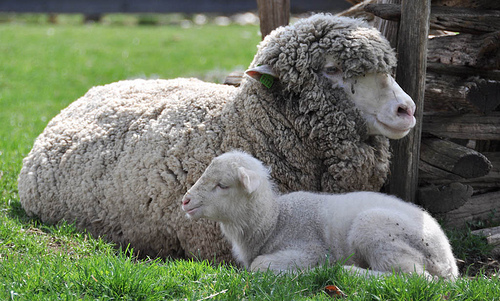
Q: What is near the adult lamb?
A: A baby lamb.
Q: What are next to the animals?
A: Stacks of wood.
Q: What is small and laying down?
A: A young lamb.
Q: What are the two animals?
A: An adult and baby lamb.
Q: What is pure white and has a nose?
A: The head of the baby lamb.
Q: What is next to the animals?
A: Wooden logs.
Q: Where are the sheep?
A: Grass field.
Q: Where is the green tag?
A: Sheep's ear.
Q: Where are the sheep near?
A: Wood structure.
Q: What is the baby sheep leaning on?
A: Adult sheep.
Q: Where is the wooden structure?
A: Next to sheep.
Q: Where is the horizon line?
A: End of field.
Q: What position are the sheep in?
A: Lying.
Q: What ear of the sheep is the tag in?
A: Right.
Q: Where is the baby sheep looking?
A: Left.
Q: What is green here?
A: Grass.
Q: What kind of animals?
A: Sheep.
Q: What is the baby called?
A: A lamb.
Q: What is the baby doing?
A: Laying down.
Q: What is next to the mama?
A: Wood pile.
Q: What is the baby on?
A: Grass.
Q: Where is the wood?
A: Next to the sheep.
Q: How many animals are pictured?
A: Two.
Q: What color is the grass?
A: Green.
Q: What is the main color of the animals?
A: White.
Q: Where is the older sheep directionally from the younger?
A: Behind.